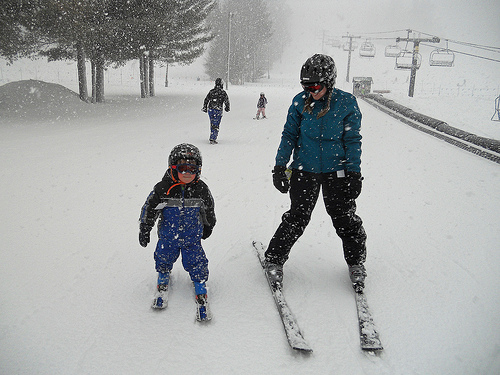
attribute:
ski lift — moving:
[302, 20, 474, 110]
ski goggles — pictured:
[299, 78, 323, 97]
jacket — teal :
[259, 76, 374, 211]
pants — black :
[244, 161, 414, 285]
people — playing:
[201, 74, 274, 151]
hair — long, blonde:
[297, 84, 340, 120]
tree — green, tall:
[16, 6, 197, 88]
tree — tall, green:
[9, 1, 220, 91]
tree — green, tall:
[0, 9, 210, 98]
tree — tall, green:
[9, 6, 212, 104]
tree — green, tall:
[3, 10, 230, 100]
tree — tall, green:
[10, 3, 217, 99]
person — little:
[135, 148, 213, 308]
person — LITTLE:
[138, 146, 215, 322]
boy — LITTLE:
[138, 142, 218, 296]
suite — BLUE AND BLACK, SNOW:
[139, 176, 216, 279]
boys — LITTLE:
[135, 143, 218, 307]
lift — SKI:
[341, 31, 460, 78]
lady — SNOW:
[262, 50, 369, 299]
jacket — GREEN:
[270, 98, 364, 166]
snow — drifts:
[7, 65, 95, 128]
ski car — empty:
[416, 36, 464, 81]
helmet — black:
[298, 50, 334, 89]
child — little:
[136, 142, 218, 299]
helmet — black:
[168, 142, 203, 172]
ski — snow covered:
[250, 233, 313, 359]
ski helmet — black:
[145, 123, 250, 206]